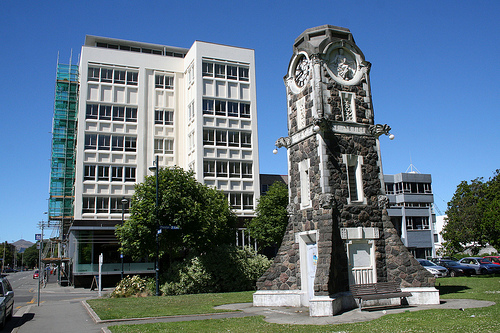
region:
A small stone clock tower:
[251, 22, 442, 319]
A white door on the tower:
[304, 240, 316, 301]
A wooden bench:
[351, 280, 411, 315]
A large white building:
[71, 34, 261, 286]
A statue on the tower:
[328, 45, 359, 80]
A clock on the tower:
[291, 50, 309, 87]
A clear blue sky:
[2, 0, 498, 241]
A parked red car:
[33, 269, 45, 279]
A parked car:
[0, 273, 17, 328]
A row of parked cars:
[413, 251, 498, 276]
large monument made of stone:
[248, 18, 450, 317]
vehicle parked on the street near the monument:
[0, 271, 20, 325]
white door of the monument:
[303, 228, 325, 306]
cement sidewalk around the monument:
[215, 290, 497, 326]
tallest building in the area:
[49, 25, 266, 290]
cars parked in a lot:
[406, 244, 498, 284]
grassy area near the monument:
[76, 269, 498, 331]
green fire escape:
[44, 58, 82, 235]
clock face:
[285, 46, 316, 96]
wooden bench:
[348, 278, 413, 315]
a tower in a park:
[256, 21, 444, 308]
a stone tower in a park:
[255, 25, 427, 312]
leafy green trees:
[122, 160, 293, 292]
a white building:
[52, 36, 258, 284]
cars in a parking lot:
[421, 254, 496, 273]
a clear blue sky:
[383, 6, 498, 155]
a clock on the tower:
[290, 55, 311, 92]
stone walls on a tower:
[260, 216, 315, 293]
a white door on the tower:
[304, 236, 324, 295]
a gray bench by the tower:
[350, 278, 414, 305]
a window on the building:
[86, 58, 103, 88]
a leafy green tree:
[111, 163, 241, 280]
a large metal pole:
[145, 153, 167, 300]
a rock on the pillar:
[276, 261, 288, 275]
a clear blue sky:
[0, 0, 498, 251]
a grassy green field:
[86, 273, 498, 331]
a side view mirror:
[1, 287, 16, 304]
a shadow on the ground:
[8, 305, 38, 332]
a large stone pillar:
[240, 15, 455, 322]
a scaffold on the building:
[36, 45, 88, 256]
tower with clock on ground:
[251, 15, 456, 315]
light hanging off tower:
[369, 122, 400, 146]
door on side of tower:
[284, 228, 324, 303]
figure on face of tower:
[328, 50, 359, 81]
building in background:
[35, 27, 260, 291]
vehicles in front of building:
[423, 252, 498, 277]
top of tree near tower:
[117, 160, 239, 251]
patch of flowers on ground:
[112, 271, 159, 297]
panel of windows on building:
[202, 125, 255, 150]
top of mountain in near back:
[15, 234, 34, 249]